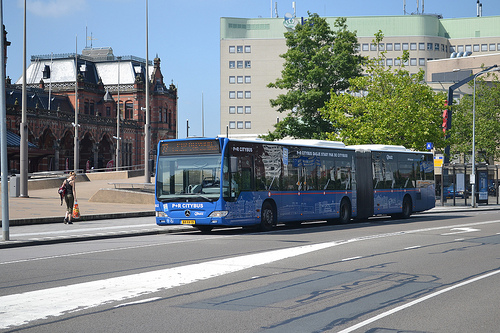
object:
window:
[157, 152, 229, 202]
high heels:
[63, 219, 73, 224]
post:
[470, 66, 500, 208]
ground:
[350, 142, 398, 190]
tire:
[328, 196, 352, 225]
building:
[218, 0, 499, 179]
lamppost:
[441, 64, 498, 203]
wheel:
[242, 198, 278, 232]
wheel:
[328, 196, 352, 225]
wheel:
[391, 193, 413, 220]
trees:
[257, 9, 499, 159]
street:
[2, 202, 499, 332]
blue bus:
[154, 137, 436, 231]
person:
[58, 171, 78, 224]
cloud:
[11, 0, 83, 25]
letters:
[172, 204, 203, 209]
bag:
[73, 201, 81, 219]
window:
[373, 162, 435, 190]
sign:
[159, 141, 220, 152]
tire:
[243, 198, 278, 232]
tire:
[391, 193, 412, 220]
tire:
[335, 190, 364, 230]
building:
[0, 26, 178, 176]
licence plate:
[181, 220, 196, 225]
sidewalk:
[421, 192, 499, 204]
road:
[64, 230, 468, 330]